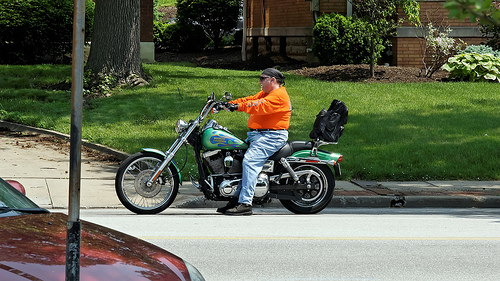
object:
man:
[214, 68, 291, 217]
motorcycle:
[114, 92, 343, 215]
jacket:
[228, 86, 292, 130]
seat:
[268, 141, 313, 161]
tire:
[277, 163, 335, 215]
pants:
[231, 129, 289, 206]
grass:
[0, 64, 500, 181]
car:
[0, 176, 204, 281]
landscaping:
[153, 16, 500, 83]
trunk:
[48, 0, 150, 95]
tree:
[55, 0, 153, 94]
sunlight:
[0, 0, 500, 281]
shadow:
[0, 85, 245, 138]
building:
[243, 0, 500, 70]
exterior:
[243, 1, 500, 76]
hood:
[0, 212, 191, 281]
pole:
[64, 0, 85, 280]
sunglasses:
[260, 76, 269, 81]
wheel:
[114, 151, 179, 215]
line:
[135, 237, 500, 240]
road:
[44, 208, 499, 281]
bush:
[312, 12, 386, 65]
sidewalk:
[0, 174, 500, 208]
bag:
[309, 99, 348, 143]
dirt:
[288, 63, 450, 84]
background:
[0, 2, 499, 101]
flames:
[209, 131, 244, 149]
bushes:
[175, 0, 241, 53]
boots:
[225, 203, 253, 216]